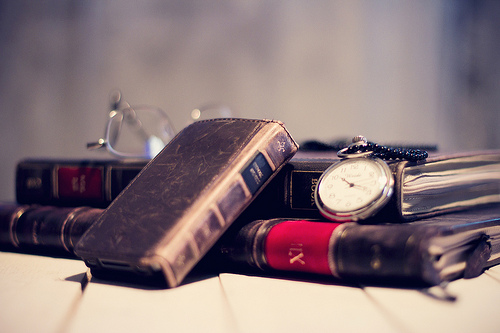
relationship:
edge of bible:
[0, 205, 429, 283] [73, 118, 301, 289]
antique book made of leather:
[1, 184, 498, 290] [139, 180, 174, 234]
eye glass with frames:
[86, 105, 255, 156] [82, 127, 103, 166]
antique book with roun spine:
[1, 185, 485, 296] [7, 195, 461, 295]